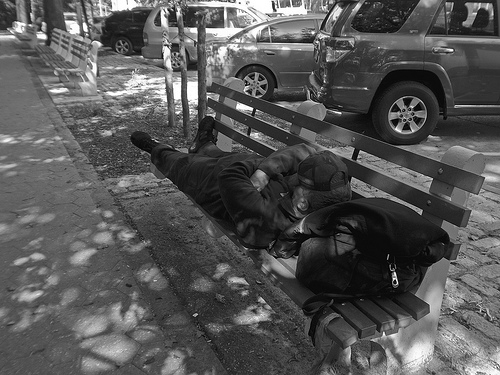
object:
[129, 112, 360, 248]
man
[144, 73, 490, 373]
bench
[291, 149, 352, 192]
hat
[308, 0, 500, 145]
car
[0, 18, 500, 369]
street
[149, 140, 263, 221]
pants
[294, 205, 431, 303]
backpack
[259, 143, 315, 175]
arm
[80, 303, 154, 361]
sunlight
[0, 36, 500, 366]
ground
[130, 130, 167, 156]
tennis shoe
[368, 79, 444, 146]
tire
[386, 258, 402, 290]
buckle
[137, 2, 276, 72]
mini van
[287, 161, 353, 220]
head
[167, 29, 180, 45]
stake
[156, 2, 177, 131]
trunk